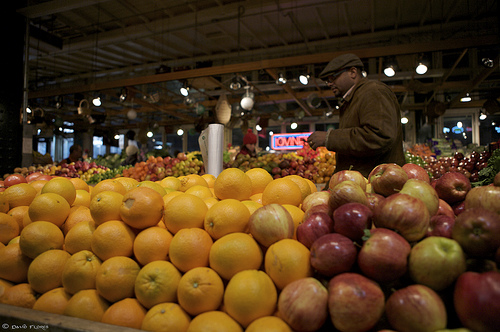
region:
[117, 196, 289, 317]
stacked oranges in background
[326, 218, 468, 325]
red apples stacked in store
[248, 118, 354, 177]
red neon sign in background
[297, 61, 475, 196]
man looking at fruits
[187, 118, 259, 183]
plastic bag in background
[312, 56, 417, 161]
man wearing brown jacket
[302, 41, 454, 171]
man wearing glasses in background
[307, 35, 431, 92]
man wearing brown hat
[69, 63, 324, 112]
lights on the ceiling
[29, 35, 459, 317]
fruit aisle in the store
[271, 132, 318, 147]
Red and blue neon sign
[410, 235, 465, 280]
Bottom of a red and yellow apple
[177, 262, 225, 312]
Round orange in a stack of oranges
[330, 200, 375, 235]
Red apple in a stack of apples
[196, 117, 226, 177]
Roll of plastic bags at a fruit stand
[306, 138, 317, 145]
Ring on a man's left hand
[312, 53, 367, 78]
Brown hat on a man's head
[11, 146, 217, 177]
Grouped fruit at a fruit stand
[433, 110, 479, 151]
Window at a fruit stand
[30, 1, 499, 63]
Ceiling at a fruit stand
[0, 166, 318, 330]
Large stack of oranges.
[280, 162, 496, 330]
Large stack of apples.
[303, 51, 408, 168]
A colored man in the fruit section.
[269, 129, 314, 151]
A neon sign in the background.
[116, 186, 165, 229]
An orange in the middle top of the stack.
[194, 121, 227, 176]
A roll of clear bags to hold fruit.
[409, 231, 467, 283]
A mostly green apple on the right.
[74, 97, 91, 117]
A basket hanging from the left ceiling.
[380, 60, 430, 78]
Two illuminated lights on the right ceiling.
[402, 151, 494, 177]
Large section of different colored apples on the right.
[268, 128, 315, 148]
The neon sign in the background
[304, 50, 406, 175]
The man in the brown coat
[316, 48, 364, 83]
The hat on the man in the brown coat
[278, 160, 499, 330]
The apple in front of the man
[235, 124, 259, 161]
The woman in the red beanie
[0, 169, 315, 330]
The oranges next to the red apples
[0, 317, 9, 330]
The copyright symbol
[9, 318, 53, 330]
The name of the photographer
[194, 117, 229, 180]
The plastic fruit bags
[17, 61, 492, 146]
The lights on the ceiling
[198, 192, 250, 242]
An orange in a pile.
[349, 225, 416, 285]
an apple in a pile.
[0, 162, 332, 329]
a pile of oranges.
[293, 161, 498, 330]
a pile of red apples.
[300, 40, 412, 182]
a man shopping for fruit.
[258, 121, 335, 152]
a neon sign.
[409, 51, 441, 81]
a track light.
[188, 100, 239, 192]
plastic bags for fruit.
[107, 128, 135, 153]
a window to the outside.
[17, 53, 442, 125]
a row of track lighting.